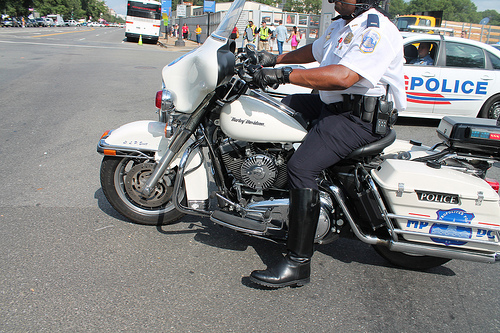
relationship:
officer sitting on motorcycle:
[237, 0, 407, 290] [94, 0, 498, 273]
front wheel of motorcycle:
[100, 149, 186, 225] [94, 0, 498, 273]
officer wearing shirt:
[237, 0, 407, 290] [310, 7, 405, 112]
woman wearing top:
[285, 24, 302, 49] [288, 30, 301, 44]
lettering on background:
[418, 190, 464, 210] [415, 186, 456, 203]